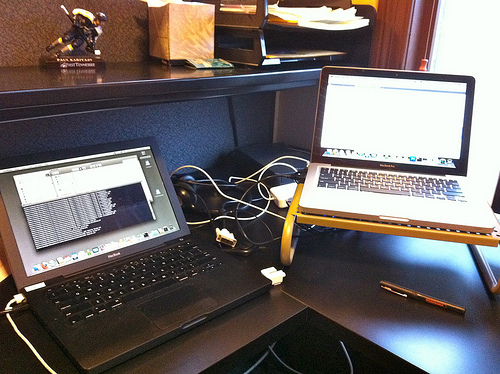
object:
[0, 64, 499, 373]
station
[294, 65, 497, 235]
computer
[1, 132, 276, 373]
computer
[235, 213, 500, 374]
table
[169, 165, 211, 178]
cords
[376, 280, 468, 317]
pen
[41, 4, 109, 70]
trophy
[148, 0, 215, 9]
tissues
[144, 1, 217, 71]
box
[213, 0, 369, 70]
basket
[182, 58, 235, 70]
booklet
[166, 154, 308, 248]
cable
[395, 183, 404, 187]
buttons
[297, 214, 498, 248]
edge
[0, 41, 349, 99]
top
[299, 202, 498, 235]
edge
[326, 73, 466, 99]
part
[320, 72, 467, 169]
screen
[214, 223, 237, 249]
part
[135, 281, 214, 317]
part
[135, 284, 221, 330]
mouse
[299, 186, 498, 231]
part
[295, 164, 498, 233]
board